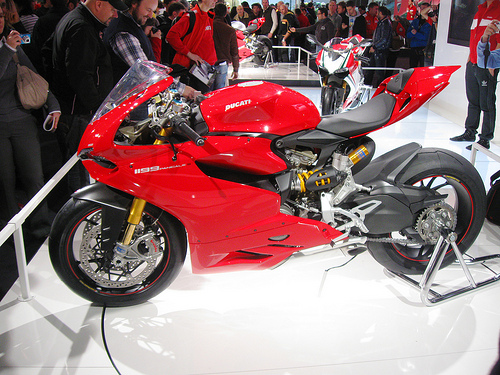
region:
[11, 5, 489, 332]
a red motorcycle at a motorcycle show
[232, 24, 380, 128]
motorcycles on display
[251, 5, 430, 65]
several people at a motorcycle show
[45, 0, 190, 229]
two men looking at a motorcycle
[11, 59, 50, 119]
the purse of a woman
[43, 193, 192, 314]
the front wheel of a motorcycle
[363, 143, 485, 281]
the rear wheel of a motorcycle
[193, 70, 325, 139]
the gas tank of a motorcycle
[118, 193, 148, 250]
the shock on a motorcycle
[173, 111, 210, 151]
the handle bar on a motorcycle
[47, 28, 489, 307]
red motorcycle on display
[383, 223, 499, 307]
silver stand holding bike in place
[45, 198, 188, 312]
black front tire of bike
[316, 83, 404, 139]
black seat of bike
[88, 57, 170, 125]
clear windshield on front of bike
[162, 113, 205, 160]
black handle bar of bike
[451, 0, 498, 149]
man in red and white jacket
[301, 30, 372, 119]
white and red bike in background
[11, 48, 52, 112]
woman carrying tan purse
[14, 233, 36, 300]
white metal support railing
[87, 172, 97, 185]
white metal support railing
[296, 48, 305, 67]
white metal support railing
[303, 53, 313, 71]
white metal support railing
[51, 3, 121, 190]
person in crowd at exhibit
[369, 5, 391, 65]
person in crowd at exhibit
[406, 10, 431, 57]
person in crowd at exhibit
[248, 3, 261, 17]
person in crowd at exhibit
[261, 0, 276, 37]
person in crowd at exhibit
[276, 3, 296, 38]
person in crowd at exhibit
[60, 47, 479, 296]
red motorcycle on display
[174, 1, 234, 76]
man wearing red sweater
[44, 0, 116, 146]
man wearing black sweater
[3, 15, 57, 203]
woman taking picture of motorcycle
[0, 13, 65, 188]
woman holding tan purse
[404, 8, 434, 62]
man wearing blue jacket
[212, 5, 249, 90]
man wearing brown jacket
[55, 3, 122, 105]
man wearing black baseball cap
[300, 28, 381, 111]
white motorcycle with red on display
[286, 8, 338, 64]
man taking a picture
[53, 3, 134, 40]
the head of a man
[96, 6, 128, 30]
the nose of a man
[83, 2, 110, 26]
the ear of a man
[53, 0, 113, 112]
the arm of a man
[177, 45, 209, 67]
the hand of a man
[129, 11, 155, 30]
the chin of a man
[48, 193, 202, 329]
the wheel on a bike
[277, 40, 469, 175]
the seat on a bike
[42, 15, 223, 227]
a man near a bike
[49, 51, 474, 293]
a sleek motor bike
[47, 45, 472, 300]
a red motor cycle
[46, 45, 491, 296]
a reddish colored sports bike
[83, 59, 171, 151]
curved window of motorbike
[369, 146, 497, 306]
rubber tire on metal stand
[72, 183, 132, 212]
light reflection on black fender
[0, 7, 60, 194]
woman holding phone in hand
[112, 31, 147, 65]
plaid sleeve of shirt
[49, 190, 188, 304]
red outline on black rubber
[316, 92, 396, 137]
surface of black leather seat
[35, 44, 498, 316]
Fancy red motorcycle with black wheels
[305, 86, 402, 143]
A black leather seat